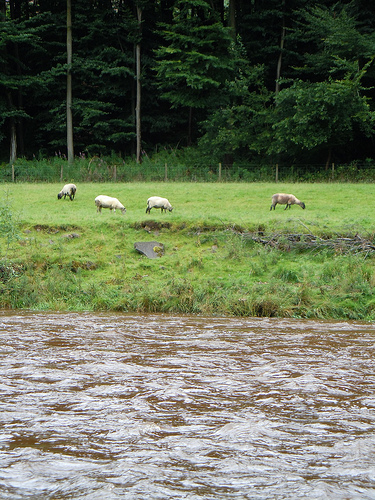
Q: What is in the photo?
A: Sheep.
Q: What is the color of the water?
A: Brown.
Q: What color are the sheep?
A: Beige.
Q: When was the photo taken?
A: Daytime.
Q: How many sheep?
A: Four.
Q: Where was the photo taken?
A: On a farm.